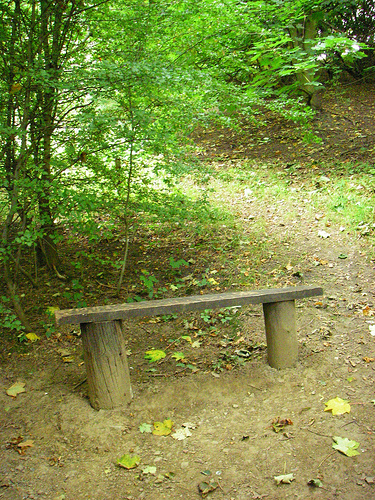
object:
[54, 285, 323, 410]
bench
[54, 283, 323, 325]
seat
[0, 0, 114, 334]
tree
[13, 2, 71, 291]
trunk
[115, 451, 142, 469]
leaf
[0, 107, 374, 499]
ground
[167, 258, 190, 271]
leaf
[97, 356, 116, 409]
crack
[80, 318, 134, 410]
log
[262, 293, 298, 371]
log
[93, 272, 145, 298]
stick